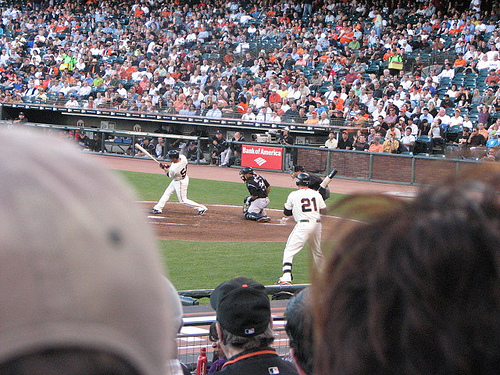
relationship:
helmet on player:
[151, 142, 191, 166] [128, 130, 222, 207]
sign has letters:
[234, 142, 286, 169] [240, 146, 280, 156]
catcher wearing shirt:
[232, 161, 279, 224] [239, 173, 269, 202]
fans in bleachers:
[3, 5, 483, 137] [0, 0, 484, 187]